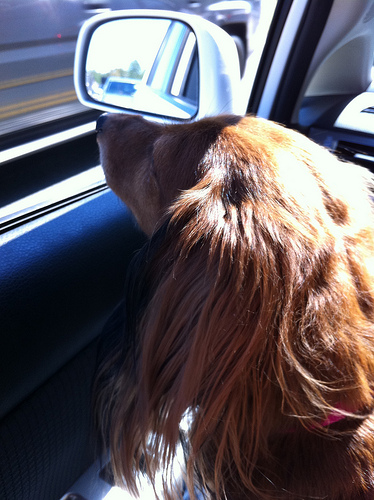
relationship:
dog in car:
[92, 113, 373, 497] [2, 1, 373, 497]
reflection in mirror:
[81, 15, 197, 122] [72, 8, 240, 128]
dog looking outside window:
[92, 113, 373, 497] [2, 1, 280, 251]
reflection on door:
[81, 15, 197, 122] [105, 24, 199, 120]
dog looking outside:
[92, 113, 373, 497] [2, 4, 94, 115]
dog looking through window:
[92, 113, 373, 497] [2, 1, 280, 251]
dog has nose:
[92, 113, 373, 497] [95, 109, 109, 136]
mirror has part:
[72, 8, 240, 128] [138, 14, 151, 66]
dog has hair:
[92, 113, 373, 497] [98, 113, 373, 495]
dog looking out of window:
[92, 113, 373, 497] [2, 1, 280, 251]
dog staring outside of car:
[92, 113, 373, 497] [2, 1, 373, 497]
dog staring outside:
[92, 113, 373, 497] [2, 4, 94, 115]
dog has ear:
[92, 113, 373, 497] [92, 195, 320, 473]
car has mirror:
[2, 1, 373, 497] [72, 8, 240, 128]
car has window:
[2, 1, 373, 497] [2, 1, 280, 251]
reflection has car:
[81, 15, 197, 122] [89, 78, 141, 99]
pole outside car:
[6, 89, 78, 119] [2, 1, 373, 497]